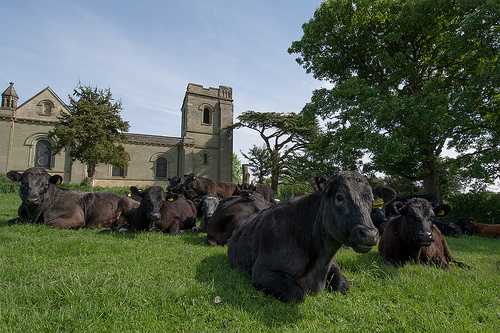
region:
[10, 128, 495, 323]
Cows are laying in field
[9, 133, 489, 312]
Cows are laying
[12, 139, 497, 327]
Cows are brown and black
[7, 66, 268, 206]
Building behind the cows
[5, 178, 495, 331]
Cows are laying in field of grass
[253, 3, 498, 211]
Trees are right next to the cows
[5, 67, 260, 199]
The building is old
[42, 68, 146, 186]
Tree in front of building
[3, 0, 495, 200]
The sky is blue and sunny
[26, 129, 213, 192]
Building has stained glass windows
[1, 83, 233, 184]
church in the back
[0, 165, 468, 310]
black cattle lying on the ground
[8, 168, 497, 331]
green short grass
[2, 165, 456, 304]
black cattles on green grass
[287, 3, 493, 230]
big tall tree inright side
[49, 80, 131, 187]
small tree in left side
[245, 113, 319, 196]
small tree with thin stem on left side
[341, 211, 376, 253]
little black trunk of cow in front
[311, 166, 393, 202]
two little black ears of cow in front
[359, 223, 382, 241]
big black nose of cow in front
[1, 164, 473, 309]
Group of cows laying on the grass.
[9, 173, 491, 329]
Green grass surrounding cows.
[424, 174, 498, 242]
Cows laying next to a tree.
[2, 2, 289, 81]
Bright blue and white sky.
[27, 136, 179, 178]
Windows on side of building.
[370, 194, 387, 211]
Yellow tag in cow's ear.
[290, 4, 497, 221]
Tall green healthy tree.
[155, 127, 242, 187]
Shadow on side of building.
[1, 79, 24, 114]
Tower on top of building.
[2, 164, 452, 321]
Cows facing the camera.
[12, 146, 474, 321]
Group of brown and black cows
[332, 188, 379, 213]
Small black eyes on cow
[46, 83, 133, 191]
Small single green tree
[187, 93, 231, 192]
Two small black windows on building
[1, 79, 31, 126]
Small pointy temple on building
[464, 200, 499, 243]
Small brown cow in the distance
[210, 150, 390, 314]
large black cow looking at the camera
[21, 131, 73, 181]
Large black door on building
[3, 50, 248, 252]
grey multi story building behind cows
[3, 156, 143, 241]
Large black cow laying off to the side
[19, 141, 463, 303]
Black cows sitting on green grass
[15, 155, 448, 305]
Cows sitting on green grass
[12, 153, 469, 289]
Black cows sitting on green grass with yellow tags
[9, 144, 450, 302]
Black cows sitting on green grass with yellow tags in their left ears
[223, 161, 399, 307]
Black cow with a tag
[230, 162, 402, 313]
Black cow with a yellow tag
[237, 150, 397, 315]
Black cow with a tag in the left ear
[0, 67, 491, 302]
Cows sitting on grass infront of a building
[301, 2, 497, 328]
Black cows sitting next to a big tree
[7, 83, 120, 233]
Cow sitting on grass near a bilding